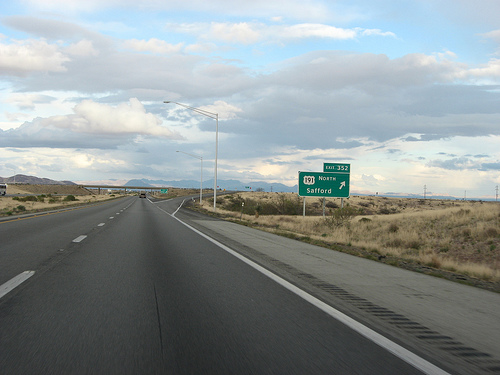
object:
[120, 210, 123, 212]
lines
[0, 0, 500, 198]
sky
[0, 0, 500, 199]
clouds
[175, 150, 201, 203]
lamp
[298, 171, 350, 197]
green sign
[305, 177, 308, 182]
black number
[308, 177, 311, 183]
black number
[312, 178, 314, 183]
black number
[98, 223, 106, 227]
line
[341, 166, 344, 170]
numbers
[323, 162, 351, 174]
sign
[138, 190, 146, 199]
car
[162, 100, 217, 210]
lamp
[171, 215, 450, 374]
line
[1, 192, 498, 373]
highway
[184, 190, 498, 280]
brown grass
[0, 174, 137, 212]
brown grass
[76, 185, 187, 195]
bridge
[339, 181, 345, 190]
arrow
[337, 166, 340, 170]
number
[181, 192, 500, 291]
field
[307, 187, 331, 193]
lettering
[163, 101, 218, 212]
lamp post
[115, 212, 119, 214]
line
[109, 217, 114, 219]
line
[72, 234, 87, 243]
line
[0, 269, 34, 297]
line